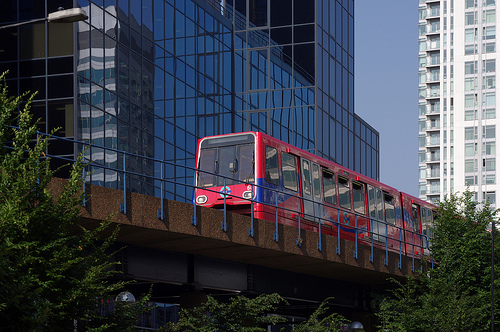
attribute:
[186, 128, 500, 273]
train — commuter, red, blue, traveling, passenger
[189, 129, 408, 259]
car — red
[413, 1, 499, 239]
building — apartment, white, high rise, tall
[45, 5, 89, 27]
light — white, street, overhead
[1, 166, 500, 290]
tracks — elevated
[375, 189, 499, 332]
trees — leafy, green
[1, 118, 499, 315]
overpass — brown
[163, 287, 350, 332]
trees — green, leafy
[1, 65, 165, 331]
trees — leafy, green, tall, large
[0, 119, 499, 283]
rails — blue, metal, grey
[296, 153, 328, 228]
doors — exit, entrance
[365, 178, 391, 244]
doors — exit, entrance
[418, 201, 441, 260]
doors — entrance, exit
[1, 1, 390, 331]
building — commercial, glass, tall, reflective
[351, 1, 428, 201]
sky — blue, deep blue